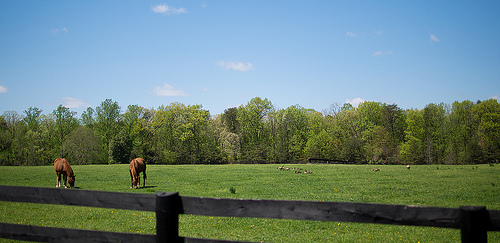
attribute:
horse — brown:
[129, 157, 146, 190]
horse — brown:
[55, 155, 75, 188]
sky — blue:
[3, 2, 498, 125]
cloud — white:
[207, 47, 262, 79]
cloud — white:
[142, 0, 197, 20]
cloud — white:
[148, 77, 190, 100]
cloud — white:
[426, 30, 444, 47]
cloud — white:
[58, 93, 95, 110]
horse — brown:
[51, 155, 78, 192]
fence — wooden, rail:
[0, 178, 500, 240]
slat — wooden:
[182, 194, 466, 225]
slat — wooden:
[4, 185, 169, 213]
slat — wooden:
[183, 193, 477, 231]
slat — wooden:
[0, 229, 107, 240]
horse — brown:
[125, 156, 147, 187]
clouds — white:
[133, 13, 350, 125]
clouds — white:
[151, 58, 256, 102]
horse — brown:
[108, 152, 193, 197]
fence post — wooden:
[154, 189, 181, 241]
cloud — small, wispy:
[343, 96, 365, 111]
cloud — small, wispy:
[216, 56, 257, 73]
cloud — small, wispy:
[150, 3, 190, 16]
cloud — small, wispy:
[148, 80, 186, 99]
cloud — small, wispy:
[60, 94, 88, 111]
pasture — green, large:
[307, 172, 447, 192]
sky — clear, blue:
[0, 0, 499, 94]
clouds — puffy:
[213, 54, 263, 76]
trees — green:
[11, 100, 498, 169]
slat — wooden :
[21, 220, 121, 240]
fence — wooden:
[6, 184, 497, 239]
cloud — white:
[216, 58, 256, 73]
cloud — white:
[150, 0, 192, 13]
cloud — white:
[331, 94, 364, 109]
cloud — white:
[0, 82, 8, 94]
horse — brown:
[49, 149, 77, 192]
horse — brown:
[124, 153, 154, 188]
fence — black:
[189, 201, 272, 242]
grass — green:
[0, 162, 497, 242]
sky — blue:
[149, 17, 389, 79]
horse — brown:
[49, 151, 78, 188]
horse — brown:
[124, 144, 167, 189]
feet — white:
[55, 182, 62, 187]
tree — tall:
[182, 107, 207, 157]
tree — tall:
[245, 100, 285, 158]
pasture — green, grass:
[7, 166, 498, 234]